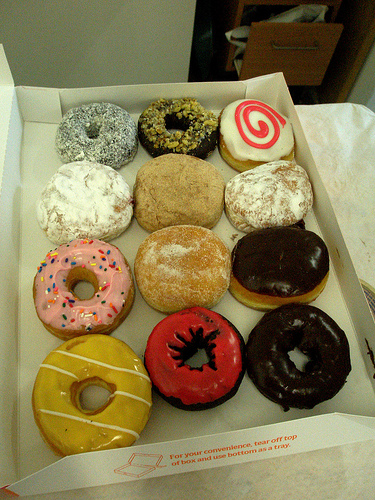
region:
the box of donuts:
[0, 41, 373, 496]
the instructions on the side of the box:
[114, 431, 296, 474]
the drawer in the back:
[231, 12, 342, 83]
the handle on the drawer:
[271, 39, 319, 50]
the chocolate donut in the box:
[245, 302, 350, 407]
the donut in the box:
[145, 308, 247, 410]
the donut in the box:
[32, 334, 151, 455]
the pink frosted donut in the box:
[33, 238, 133, 336]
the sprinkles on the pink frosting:
[34, 238, 126, 329]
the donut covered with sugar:
[135, 225, 231, 310]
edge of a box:
[161, 435, 193, 470]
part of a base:
[224, 410, 241, 432]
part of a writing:
[177, 455, 198, 478]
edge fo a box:
[175, 431, 186, 441]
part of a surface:
[274, 457, 295, 481]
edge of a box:
[172, 437, 177, 441]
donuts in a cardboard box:
[16, 91, 370, 475]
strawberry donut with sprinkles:
[31, 241, 137, 335]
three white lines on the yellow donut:
[25, 330, 169, 453]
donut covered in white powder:
[33, 164, 134, 241]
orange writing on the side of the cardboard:
[166, 426, 317, 472]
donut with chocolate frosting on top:
[226, 227, 336, 309]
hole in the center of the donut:
[282, 339, 313, 381]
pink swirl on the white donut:
[220, 97, 296, 164]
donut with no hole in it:
[136, 224, 232, 308]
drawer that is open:
[223, 4, 341, 97]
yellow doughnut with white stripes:
[30, 329, 147, 449]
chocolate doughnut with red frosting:
[145, 305, 243, 407]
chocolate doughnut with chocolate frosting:
[244, 303, 352, 409]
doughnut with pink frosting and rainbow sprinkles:
[30, 236, 135, 338]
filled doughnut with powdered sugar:
[134, 224, 231, 311]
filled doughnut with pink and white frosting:
[216, 92, 296, 170]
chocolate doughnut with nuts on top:
[139, 95, 217, 158]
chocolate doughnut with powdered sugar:
[54, 98, 137, 166]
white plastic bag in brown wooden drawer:
[223, 0, 346, 91]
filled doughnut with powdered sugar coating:
[34, 160, 132, 240]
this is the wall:
[76, 6, 154, 72]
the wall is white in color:
[82, 3, 156, 65]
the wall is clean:
[109, 11, 158, 56]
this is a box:
[163, 414, 188, 426]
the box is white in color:
[75, 457, 94, 478]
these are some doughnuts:
[32, 102, 352, 427]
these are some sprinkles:
[81, 248, 116, 271]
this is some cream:
[255, 340, 279, 366]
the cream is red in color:
[172, 376, 198, 388]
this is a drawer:
[231, 10, 341, 75]